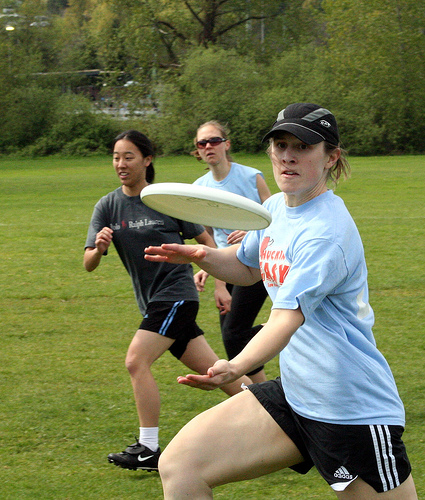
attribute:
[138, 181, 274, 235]
frisbee — white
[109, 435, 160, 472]
shoe — nike brand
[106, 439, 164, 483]
cleats — black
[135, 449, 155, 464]
logo — white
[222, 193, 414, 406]
shirt — light blue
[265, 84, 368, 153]
hat — black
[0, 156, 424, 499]
grass — green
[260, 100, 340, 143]
hat — black, grey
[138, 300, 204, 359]
shorts — black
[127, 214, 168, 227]
word — ralph lauren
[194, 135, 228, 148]
sunglasses — brown, colored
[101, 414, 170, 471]
shoe — black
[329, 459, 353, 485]
logo — IN 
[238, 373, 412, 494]
shorts — black, ADIDAS brand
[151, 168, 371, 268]
frisbee — white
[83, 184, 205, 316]
shirt — dark gray, gray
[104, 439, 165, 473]
shoe — black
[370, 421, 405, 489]
stripe — decorative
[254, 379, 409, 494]
pants — HAVE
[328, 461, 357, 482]
adidas symbol — white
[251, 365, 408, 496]
shorts — black